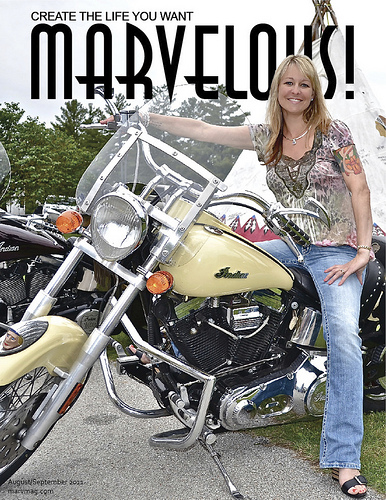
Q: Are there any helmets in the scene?
A: No, there are no helmets.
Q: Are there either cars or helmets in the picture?
A: No, there are no helmets or cars.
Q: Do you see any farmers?
A: No, there are no farmers.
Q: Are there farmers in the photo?
A: No, there are no farmers.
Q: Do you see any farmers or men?
A: No, there are no farmers or men.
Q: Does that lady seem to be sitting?
A: Yes, the lady is sitting.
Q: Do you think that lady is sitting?
A: Yes, the lady is sitting.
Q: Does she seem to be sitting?
A: Yes, the lady is sitting.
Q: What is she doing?
A: The lady is sitting.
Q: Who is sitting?
A: The lady is sitting.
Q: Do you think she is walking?
A: No, the lady is sitting.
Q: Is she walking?
A: No, the lady is sitting.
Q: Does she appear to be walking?
A: No, the lady is sitting.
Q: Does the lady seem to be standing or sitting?
A: The lady is sitting.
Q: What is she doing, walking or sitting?
A: The lady is sitting.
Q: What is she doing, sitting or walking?
A: The lady is sitting.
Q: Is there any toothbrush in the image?
A: No, there are no toothbrushes.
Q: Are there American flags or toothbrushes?
A: No, there are no toothbrushes or American flags.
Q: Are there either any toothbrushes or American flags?
A: No, there are no toothbrushes or American flags.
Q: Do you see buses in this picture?
A: No, there are no buses.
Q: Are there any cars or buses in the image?
A: No, there are no buses or cars.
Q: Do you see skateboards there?
A: No, there are no skateboards.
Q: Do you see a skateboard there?
A: No, there are no skateboards.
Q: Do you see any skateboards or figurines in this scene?
A: No, there are no skateboards or figurines.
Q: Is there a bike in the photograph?
A: Yes, there is a bike.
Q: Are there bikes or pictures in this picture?
A: Yes, there is a bike.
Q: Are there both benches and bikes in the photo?
A: No, there is a bike but no benches.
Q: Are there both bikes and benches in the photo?
A: No, there is a bike but no benches.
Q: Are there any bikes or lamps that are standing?
A: Yes, the bike is standing.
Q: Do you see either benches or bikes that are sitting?
A: Yes, the bike is sitting.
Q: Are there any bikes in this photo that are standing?
A: Yes, there is a bike that is standing.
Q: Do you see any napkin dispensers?
A: No, there are no napkin dispensers.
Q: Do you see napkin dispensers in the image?
A: No, there are no napkin dispensers.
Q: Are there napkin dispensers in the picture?
A: No, there are no napkin dispensers.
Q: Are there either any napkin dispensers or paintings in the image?
A: No, there are no napkin dispensers or paintings.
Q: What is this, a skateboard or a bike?
A: This is a bike.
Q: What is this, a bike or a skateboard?
A: This is a bike.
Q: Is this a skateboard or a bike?
A: This is a bike.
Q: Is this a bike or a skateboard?
A: This is a bike.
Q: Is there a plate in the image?
A: No, there are no plates.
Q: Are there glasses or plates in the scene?
A: No, there are no plates or glasses.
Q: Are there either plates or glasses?
A: No, there are no plates or glasses.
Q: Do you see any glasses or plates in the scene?
A: No, there are no plates or glasses.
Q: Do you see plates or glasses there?
A: No, there are no plates or glasses.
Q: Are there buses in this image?
A: No, there are no buses.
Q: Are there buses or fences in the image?
A: No, there are no buses or fences.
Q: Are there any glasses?
A: No, there are no glasses.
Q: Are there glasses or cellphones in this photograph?
A: No, there are no glasses or cellphones.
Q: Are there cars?
A: No, there are no cars.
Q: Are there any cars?
A: No, there are no cars.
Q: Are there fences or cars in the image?
A: No, there are no cars or fences.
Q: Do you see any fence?
A: No, there are no fences.